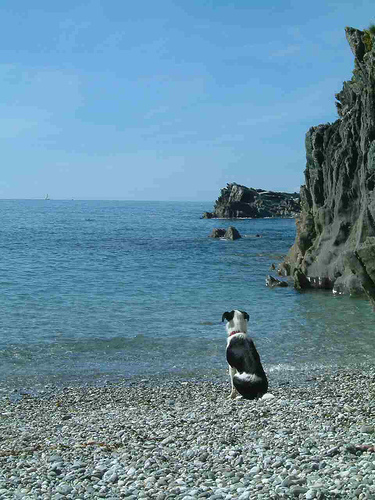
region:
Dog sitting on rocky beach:
[220, 309, 274, 400]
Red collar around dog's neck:
[227, 329, 246, 334]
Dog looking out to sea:
[220, 308, 274, 400]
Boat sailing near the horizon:
[45, 192, 49, 200]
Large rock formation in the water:
[197, 181, 299, 219]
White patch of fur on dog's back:
[231, 368, 263, 382]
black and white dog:
[219, 305, 275, 404]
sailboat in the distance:
[44, 192, 50, 201]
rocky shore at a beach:
[1, 354, 374, 499]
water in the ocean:
[1, 198, 374, 374]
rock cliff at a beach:
[265, 17, 373, 299]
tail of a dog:
[258, 388, 277, 403]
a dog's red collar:
[226, 330, 246, 337]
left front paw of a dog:
[223, 358, 237, 407]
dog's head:
[223, 306, 253, 337]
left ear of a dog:
[219, 309, 232, 323]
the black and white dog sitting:
[220, 309, 275, 400]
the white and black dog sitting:
[221, 309, 276, 400]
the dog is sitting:
[222, 309, 276, 402]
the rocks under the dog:
[0, 310, 373, 497]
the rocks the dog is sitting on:
[1, 308, 374, 497]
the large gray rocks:
[200, 26, 374, 305]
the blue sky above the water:
[0, 0, 373, 380]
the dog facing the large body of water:
[0, 199, 373, 399]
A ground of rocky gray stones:
[147, 431, 275, 491]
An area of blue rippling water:
[56, 233, 193, 320]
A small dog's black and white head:
[214, 304, 261, 332]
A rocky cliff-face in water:
[268, 189, 370, 299]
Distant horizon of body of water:
[33, 188, 179, 219]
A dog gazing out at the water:
[79, 290, 287, 428]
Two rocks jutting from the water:
[208, 223, 250, 246]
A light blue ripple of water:
[75, 331, 202, 352]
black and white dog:
[211, 308, 283, 408]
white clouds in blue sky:
[15, 38, 65, 86]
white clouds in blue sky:
[276, 16, 315, 57]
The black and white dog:
[218, 307, 293, 399]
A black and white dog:
[208, 305, 288, 405]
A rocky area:
[7, 375, 360, 499]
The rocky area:
[4, 377, 371, 498]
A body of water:
[0, 244, 369, 372]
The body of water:
[4, 247, 374, 373]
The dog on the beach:
[214, 303, 294, 398]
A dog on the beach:
[205, 300, 288, 405]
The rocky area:
[7, 365, 371, 498]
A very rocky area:
[7, 372, 368, 495]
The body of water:
[4, 282, 370, 365]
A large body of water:
[1, 282, 370, 369]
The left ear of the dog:
[217, 307, 231, 324]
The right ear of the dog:
[242, 306, 258, 324]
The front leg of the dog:
[223, 363, 236, 402]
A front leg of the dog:
[225, 362, 240, 400]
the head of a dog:
[212, 304, 253, 337]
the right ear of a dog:
[235, 303, 256, 323]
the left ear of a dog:
[221, 309, 235, 324]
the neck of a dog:
[227, 318, 252, 339]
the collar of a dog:
[226, 328, 245, 336]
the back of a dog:
[234, 336, 266, 391]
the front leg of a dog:
[223, 364, 243, 392]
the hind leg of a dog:
[225, 386, 246, 402]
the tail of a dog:
[241, 386, 279, 404]